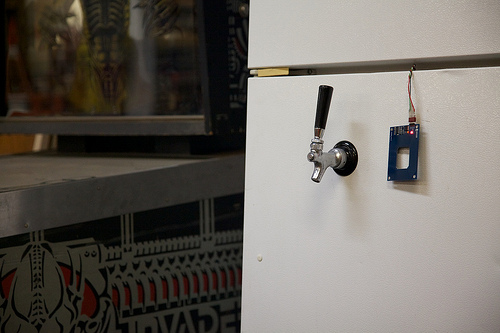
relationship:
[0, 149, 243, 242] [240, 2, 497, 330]
countertop near refrigerator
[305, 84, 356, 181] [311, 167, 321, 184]
tap has nozzle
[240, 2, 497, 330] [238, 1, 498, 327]
refrigerator has front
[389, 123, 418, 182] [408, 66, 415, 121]
item hanging from wires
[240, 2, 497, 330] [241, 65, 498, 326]
refrigerator has door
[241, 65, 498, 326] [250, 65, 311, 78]
door has hinge